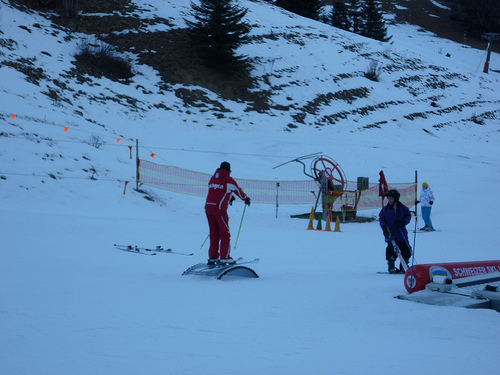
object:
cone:
[305, 206, 315, 230]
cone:
[315, 213, 325, 230]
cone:
[322, 207, 334, 232]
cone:
[333, 214, 342, 230]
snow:
[279, 209, 388, 282]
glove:
[245, 196, 252, 207]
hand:
[245, 195, 251, 207]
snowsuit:
[204, 169, 246, 262]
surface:
[184, 254, 260, 284]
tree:
[186, 3, 264, 102]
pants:
[418, 201, 435, 232]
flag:
[4, 108, 158, 161]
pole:
[236, 196, 249, 253]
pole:
[193, 195, 228, 251]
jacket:
[200, 165, 253, 211]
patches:
[71, 38, 143, 85]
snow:
[43, 271, 131, 361]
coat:
[378, 201, 412, 238]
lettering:
[207, 180, 227, 189]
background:
[205, 168, 228, 201]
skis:
[181, 261, 260, 279]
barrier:
[141, 159, 410, 214]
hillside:
[0, 5, 448, 203]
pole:
[134, 136, 141, 189]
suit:
[381, 199, 415, 273]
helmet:
[217, 160, 229, 175]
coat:
[416, 190, 436, 212]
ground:
[2, 280, 452, 362]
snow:
[8, 314, 51, 366]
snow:
[249, 316, 323, 372]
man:
[204, 160, 253, 265]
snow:
[322, 358, 379, 375]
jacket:
[418, 187, 438, 209]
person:
[414, 179, 438, 231]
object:
[405, 259, 500, 294]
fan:
[310, 155, 353, 209]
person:
[379, 186, 413, 275]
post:
[482, 37, 494, 78]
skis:
[117, 235, 173, 256]